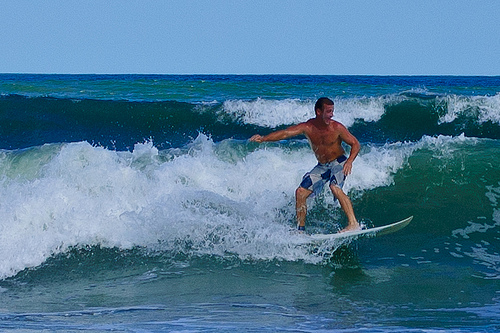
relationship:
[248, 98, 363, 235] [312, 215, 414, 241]
man on surfboard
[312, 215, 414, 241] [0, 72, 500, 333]
surfboard in water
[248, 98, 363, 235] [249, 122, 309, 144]
man has right arm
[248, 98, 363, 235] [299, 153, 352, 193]
man wearing shorts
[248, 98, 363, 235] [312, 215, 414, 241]
man on top of surfboard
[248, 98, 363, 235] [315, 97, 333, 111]
man has hair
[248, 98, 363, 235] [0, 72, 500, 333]
man in water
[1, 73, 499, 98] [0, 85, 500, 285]
calm water behind waves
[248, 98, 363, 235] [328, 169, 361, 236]
man has legs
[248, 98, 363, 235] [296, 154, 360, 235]
man has legs